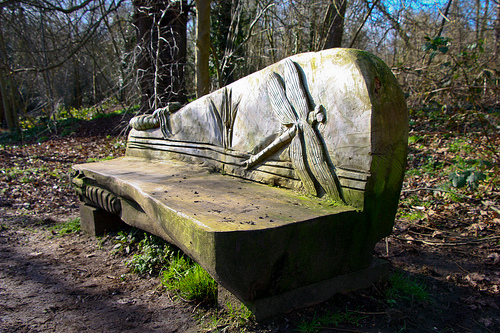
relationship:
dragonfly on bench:
[244, 58, 345, 204] [73, 46, 404, 323]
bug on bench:
[130, 104, 172, 133] [73, 46, 404, 323]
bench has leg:
[73, 46, 404, 323] [73, 205, 110, 237]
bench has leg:
[73, 46, 404, 323] [217, 258, 390, 314]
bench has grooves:
[73, 46, 404, 323] [126, 135, 372, 191]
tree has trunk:
[0, 18, 25, 148] [0, 87, 25, 147]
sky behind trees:
[3, 2, 496, 46] [2, 2, 497, 120]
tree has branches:
[121, 3, 218, 107] [139, 3, 180, 109]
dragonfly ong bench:
[244, 58, 345, 204] [73, 46, 404, 323]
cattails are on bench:
[203, 89, 238, 147] [73, 46, 404, 323]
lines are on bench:
[126, 135, 372, 191] [73, 46, 404, 323]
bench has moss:
[73, 46, 404, 323] [286, 177, 368, 212]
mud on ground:
[1, 140, 498, 326] [0, 113, 500, 323]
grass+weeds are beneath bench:
[60, 210, 217, 297] [73, 46, 404, 323]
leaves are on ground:
[4, 128, 500, 281] [0, 113, 500, 323]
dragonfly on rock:
[244, 58, 345, 204] [73, 46, 404, 323]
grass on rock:
[158, 263, 218, 304] [176, 256, 251, 323]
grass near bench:
[158, 263, 218, 304] [73, 46, 404, 323]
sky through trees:
[3, 2, 496, 46] [2, 2, 497, 120]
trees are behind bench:
[2, 2, 497, 120] [73, 46, 404, 323]